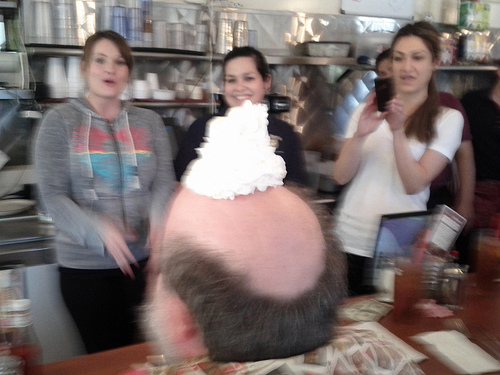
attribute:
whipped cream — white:
[180, 100, 288, 201]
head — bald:
[135, 175, 342, 360]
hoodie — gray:
[31, 96, 177, 273]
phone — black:
[372, 77, 398, 115]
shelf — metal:
[32, 89, 222, 111]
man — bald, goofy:
[129, 177, 428, 375]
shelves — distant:
[22, 2, 500, 195]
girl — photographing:
[330, 21, 467, 299]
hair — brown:
[389, 20, 442, 146]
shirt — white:
[330, 100, 465, 259]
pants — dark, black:
[59, 257, 149, 355]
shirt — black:
[175, 110, 311, 190]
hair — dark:
[223, 44, 272, 82]